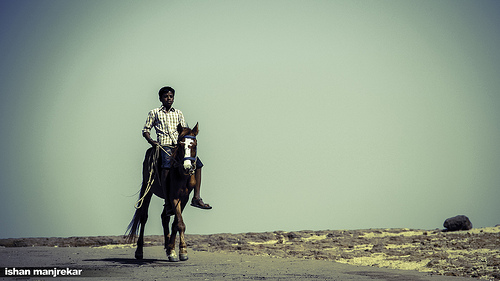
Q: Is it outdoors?
A: Yes, it is outdoors.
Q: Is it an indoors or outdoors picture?
A: It is outdoors.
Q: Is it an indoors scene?
A: No, it is outdoors.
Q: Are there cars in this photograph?
A: No, there are no cars.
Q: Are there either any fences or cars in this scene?
A: No, there are no cars or fences.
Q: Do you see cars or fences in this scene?
A: No, there are no cars or fences.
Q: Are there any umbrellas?
A: No, there are no umbrellas.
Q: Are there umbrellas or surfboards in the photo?
A: No, there are no umbrellas or surfboards.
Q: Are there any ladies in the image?
A: No, there are no ladies.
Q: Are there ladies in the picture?
A: No, there are no ladies.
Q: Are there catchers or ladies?
A: No, there are no ladies or catchers.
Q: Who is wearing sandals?
A: The boy is wearing sandals.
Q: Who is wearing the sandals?
A: The boy is wearing sandals.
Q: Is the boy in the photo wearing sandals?
A: Yes, the boy is wearing sandals.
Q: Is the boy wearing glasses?
A: No, the boy is wearing sandals.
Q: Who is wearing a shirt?
A: The boy is wearing a shirt.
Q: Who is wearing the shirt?
A: The boy is wearing a shirt.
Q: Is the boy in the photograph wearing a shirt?
A: Yes, the boy is wearing a shirt.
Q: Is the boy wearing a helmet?
A: No, the boy is wearing a shirt.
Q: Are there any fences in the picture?
A: No, there are no fences.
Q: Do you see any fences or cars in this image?
A: No, there are no fences or cars.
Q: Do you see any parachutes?
A: No, there are no parachutes.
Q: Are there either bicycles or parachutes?
A: No, there are no parachutes or bicycles.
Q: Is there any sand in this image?
A: Yes, there is sand.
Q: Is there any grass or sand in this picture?
A: Yes, there is sand.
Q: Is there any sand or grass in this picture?
A: Yes, there is sand.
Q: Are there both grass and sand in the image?
A: No, there is sand but no grass.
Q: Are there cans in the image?
A: No, there are no cans.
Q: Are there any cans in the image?
A: No, there are no cans.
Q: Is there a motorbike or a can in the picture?
A: No, there are no cans or motorcycles.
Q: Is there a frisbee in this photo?
A: No, there are no frisbees.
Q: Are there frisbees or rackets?
A: No, there are no frisbees or rackets.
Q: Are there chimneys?
A: No, there are no chimneys.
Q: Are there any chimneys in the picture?
A: No, there are no chimneys.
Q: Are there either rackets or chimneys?
A: No, there are no chimneys or rackets.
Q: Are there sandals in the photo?
A: Yes, there are sandals.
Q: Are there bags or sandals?
A: Yes, there are sandals.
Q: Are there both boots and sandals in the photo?
A: No, there are sandals but no boots.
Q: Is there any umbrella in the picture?
A: No, there are no umbrellas.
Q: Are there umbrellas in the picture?
A: No, there are no umbrellas.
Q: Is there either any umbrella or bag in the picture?
A: No, there are no umbrellas or bags.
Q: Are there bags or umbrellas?
A: No, there are no umbrellas or bags.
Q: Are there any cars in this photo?
A: No, there are no cars.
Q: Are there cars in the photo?
A: No, there are no cars.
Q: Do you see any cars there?
A: No, there are no cars.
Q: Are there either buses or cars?
A: No, there are no cars or buses.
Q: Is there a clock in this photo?
A: No, there are no clocks.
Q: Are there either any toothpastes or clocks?
A: No, there are no clocks or toothpastes.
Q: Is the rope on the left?
A: Yes, the rope is on the left of the image.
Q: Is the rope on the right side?
A: No, the rope is on the left of the image.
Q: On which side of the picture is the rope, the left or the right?
A: The rope is on the left of the image.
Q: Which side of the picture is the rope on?
A: The rope is on the left of the image.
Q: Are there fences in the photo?
A: No, there are no fences.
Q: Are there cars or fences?
A: No, there are no fences or cars.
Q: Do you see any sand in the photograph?
A: Yes, there is sand.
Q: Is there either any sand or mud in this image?
A: Yes, there is sand.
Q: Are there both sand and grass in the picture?
A: No, there is sand but no grass.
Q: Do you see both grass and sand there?
A: No, there is sand but no grass.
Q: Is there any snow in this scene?
A: No, there is no snow.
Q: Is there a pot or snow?
A: No, there are no snow or pots.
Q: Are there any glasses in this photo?
A: No, there are no glasses.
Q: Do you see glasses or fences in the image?
A: No, there are no glasses or fences.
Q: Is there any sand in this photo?
A: Yes, there is sand.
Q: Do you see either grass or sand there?
A: Yes, there is sand.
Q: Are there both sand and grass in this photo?
A: No, there is sand but no grass.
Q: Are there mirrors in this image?
A: No, there are no mirrors.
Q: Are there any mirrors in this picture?
A: No, there are no mirrors.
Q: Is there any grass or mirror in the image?
A: No, there are no mirrors or grass.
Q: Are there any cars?
A: No, there are no cars.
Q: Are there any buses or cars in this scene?
A: No, there are no cars or buses.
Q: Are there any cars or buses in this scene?
A: No, there are no cars or buses.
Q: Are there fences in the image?
A: No, there are no fences.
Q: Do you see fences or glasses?
A: No, there are no fences or glasses.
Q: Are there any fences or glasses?
A: No, there are no fences or glasses.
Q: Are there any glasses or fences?
A: No, there are no fences or glasses.